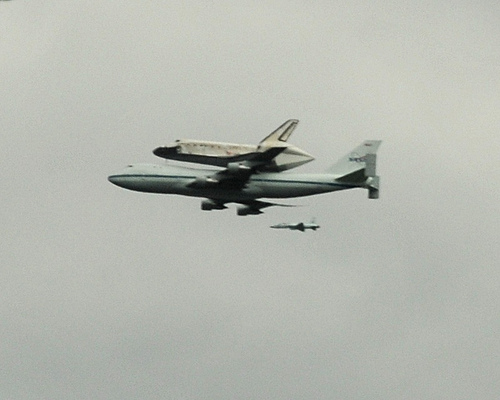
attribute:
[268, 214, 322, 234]
plane — small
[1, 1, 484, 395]
sky — gray, clear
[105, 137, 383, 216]
plane — big, largest, blue, gray, large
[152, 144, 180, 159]
nose — black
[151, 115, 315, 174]
plane — black, white, smaller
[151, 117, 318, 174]
space shuttle — white, black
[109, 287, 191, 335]
sky — overcast, grey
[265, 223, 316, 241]
airforce — light, gray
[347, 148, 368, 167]
insignia — nasa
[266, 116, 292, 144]
part — white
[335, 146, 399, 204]
part — white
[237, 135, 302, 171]
part — white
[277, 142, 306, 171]
part — white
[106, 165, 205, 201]
part — white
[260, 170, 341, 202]
part — white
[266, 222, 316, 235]
part — white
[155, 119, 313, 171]
plane — white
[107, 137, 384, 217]
airplane — large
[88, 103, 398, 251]
planes — e